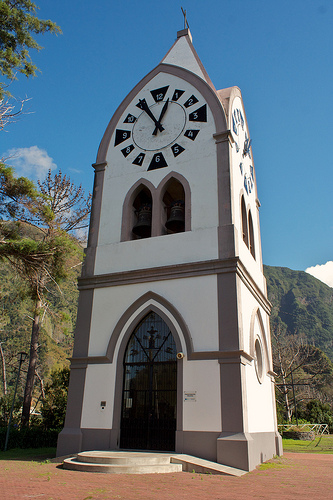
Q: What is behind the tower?
A: Mountains.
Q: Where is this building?
A: In a hilly area.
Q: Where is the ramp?
A: Next to the stairs.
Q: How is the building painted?
A: White.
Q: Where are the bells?
A: Below the clock.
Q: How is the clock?
A: Round and circular.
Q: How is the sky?
A: Clear and blue.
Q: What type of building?
A: A clock tower.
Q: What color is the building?
A: Brown and white.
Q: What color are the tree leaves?
A: Green.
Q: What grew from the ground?
A: Grass and trees.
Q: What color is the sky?
A: Blue.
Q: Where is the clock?
A: On the building.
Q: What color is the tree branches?
A: Brown.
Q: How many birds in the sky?
A: 0.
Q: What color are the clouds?
A: White.